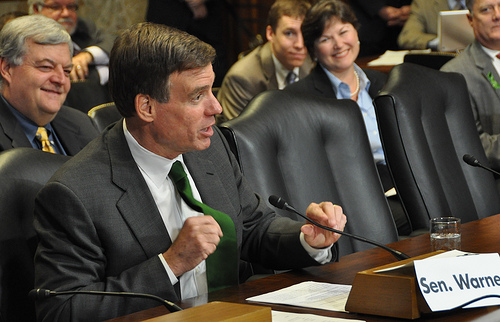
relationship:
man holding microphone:
[28, 18, 353, 322] [267, 189, 414, 264]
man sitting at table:
[28, 18, 353, 322] [63, 205, 497, 321]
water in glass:
[431, 232, 465, 254] [429, 213, 466, 258]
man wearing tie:
[2, 11, 102, 158] [34, 125, 57, 155]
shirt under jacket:
[123, 127, 216, 305] [25, 114, 341, 311]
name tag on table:
[411, 254, 499, 314] [63, 205, 497, 321]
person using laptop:
[395, 1, 485, 57] [435, 8, 485, 53]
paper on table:
[242, 275, 376, 321] [63, 205, 497, 321]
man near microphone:
[28, 18, 353, 322] [267, 189, 414, 264]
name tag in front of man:
[411, 254, 499, 314] [28, 18, 353, 322]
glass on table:
[429, 213, 466, 258] [63, 205, 497, 321]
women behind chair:
[285, 4, 429, 239] [220, 85, 412, 258]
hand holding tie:
[158, 210, 226, 273] [164, 159, 250, 288]